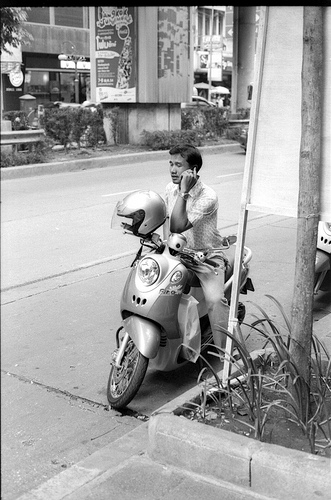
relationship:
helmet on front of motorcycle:
[110, 187, 167, 241] [107, 234, 255, 408]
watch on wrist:
[178, 192, 190, 201] [178, 189, 190, 199]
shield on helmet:
[109, 199, 142, 233] [110, 188, 167, 235]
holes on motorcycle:
[115, 285, 154, 314] [73, 244, 311, 357]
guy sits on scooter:
[159, 135, 232, 363] [97, 217, 261, 405]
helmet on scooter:
[100, 181, 172, 241] [78, 225, 272, 407]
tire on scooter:
[106, 338, 149, 410] [108, 214, 258, 404]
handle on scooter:
[200, 255, 221, 267] [97, 217, 261, 405]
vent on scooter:
[126, 292, 153, 308] [85, 179, 261, 411]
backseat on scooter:
[223, 233, 248, 279] [106, 188, 255, 405]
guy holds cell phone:
[156, 135, 247, 355] [179, 171, 200, 187]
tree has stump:
[298, 20, 321, 242] [293, 127, 329, 225]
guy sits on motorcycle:
[159, 135, 232, 363] [107, 234, 255, 408]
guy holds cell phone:
[159, 135, 232, 363] [183, 168, 197, 184]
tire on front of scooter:
[108, 340, 146, 412] [105, 186, 254, 411]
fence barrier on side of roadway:
[0, 128, 55, 160] [0, 144, 330, 499]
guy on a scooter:
[159, 135, 232, 363] [97, 182, 264, 419]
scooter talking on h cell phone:
[97, 182, 264, 419] [188, 165, 198, 179]